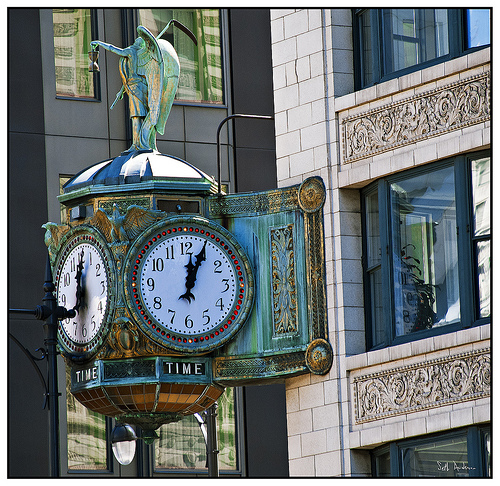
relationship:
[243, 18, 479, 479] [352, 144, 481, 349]
house has window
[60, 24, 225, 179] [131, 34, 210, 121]
sculpture has wings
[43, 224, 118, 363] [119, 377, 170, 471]
clock on pole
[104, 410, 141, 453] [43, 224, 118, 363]
light under clock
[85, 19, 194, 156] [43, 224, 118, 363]
sculpture on clock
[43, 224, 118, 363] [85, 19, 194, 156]
clock under sculpture